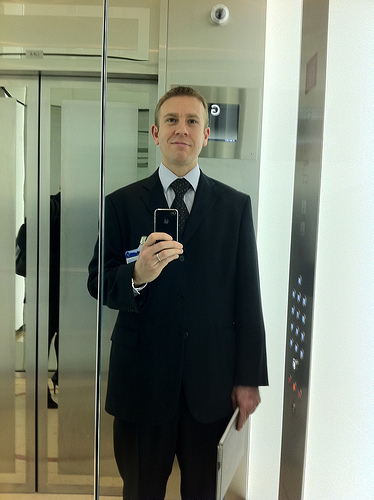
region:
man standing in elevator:
[6, 11, 296, 490]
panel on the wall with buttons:
[277, 220, 316, 496]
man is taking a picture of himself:
[87, 83, 265, 491]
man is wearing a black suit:
[106, 91, 269, 495]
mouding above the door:
[3, 0, 154, 63]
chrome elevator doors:
[103, 6, 257, 497]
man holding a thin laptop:
[213, 397, 251, 496]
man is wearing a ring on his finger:
[148, 243, 159, 257]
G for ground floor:
[205, 102, 221, 115]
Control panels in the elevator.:
[268, 252, 322, 440]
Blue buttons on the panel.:
[279, 268, 308, 364]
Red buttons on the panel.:
[279, 372, 315, 401]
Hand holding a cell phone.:
[136, 191, 184, 293]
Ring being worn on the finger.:
[136, 225, 186, 289]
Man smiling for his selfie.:
[145, 76, 221, 182]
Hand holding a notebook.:
[191, 373, 275, 495]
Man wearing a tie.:
[151, 84, 212, 214]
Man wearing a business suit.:
[81, 70, 264, 415]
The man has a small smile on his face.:
[137, 74, 220, 187]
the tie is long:
[165, 179, 190, 210]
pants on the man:
[90, 445, 221, 493]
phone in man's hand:
[139, 204, 179, 284]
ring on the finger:
[149, 250, 163, 263]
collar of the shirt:
[153, 167, 204, 191]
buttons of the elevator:
[282, 274, 324, 416]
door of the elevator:
[22, 387, 110, 495]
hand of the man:
[228, 379, 264, 426]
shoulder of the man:
[201, 191, 253, 222]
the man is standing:
[69, 274, 260, 484]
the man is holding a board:
[180, 391, 276, 482]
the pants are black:
[112, 327, 270, 478]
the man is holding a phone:
[91, 214, 208, 290]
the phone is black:
[149, 195, 194, 240]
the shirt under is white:
[143, 156, 230, 232]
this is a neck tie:
[152, 153, 209, 235]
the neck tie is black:
[157, 174, 211, 230]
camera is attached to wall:
[209, 2, 228, 26]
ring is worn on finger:
[155, 253, 163, 263]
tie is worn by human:
[168, 173, 190, 234]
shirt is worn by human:
[155, 159, 202, 222]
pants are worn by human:
[112, 366, 238, 499]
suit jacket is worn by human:
[87, 165, 270, 424]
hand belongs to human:
[230, 382, 261, 429]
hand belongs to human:
[135, 231, 182, 288]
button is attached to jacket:
[180, 325, 190, 338]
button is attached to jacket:
[177, 253, 186, 263]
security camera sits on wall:
[209, 3, 229, 28]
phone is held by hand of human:
[152, 207, 179, 244]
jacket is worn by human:
[82, 164, 274, 427]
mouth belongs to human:
[169, 139, 192, 151]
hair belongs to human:
[152, 82, 209, 134]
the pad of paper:
[216, 405, 247, 497]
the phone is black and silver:
[153, 208, 179, 244]